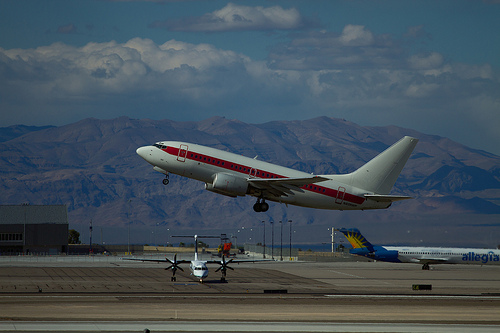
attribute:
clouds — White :
[17, 40, 276, 99]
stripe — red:
[159, 143, 365, 203]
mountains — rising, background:
[8, 109, 482, 225]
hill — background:
[14, 107, 487, 237]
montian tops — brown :
[1, 110, 422, 132]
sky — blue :
[201, 21, 498, 132]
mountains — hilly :
[6, 109, 161, 216]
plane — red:
[134, 132, 418, 212]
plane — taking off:
[134, 136, 420, 217]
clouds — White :
[6, 5, 496, 109]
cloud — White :
[164, 3, 306, 34]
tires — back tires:
[237, 190, 281, 222]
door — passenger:
[175, 143, 190, 163]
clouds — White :
[5, 37, 477, 111]